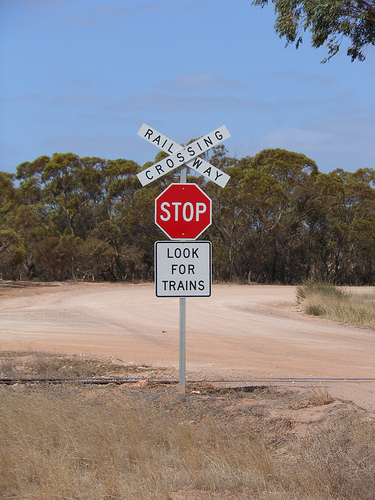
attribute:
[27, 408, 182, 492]
dry grass — dead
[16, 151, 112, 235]
tree — pictured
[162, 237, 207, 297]
sign — black , white 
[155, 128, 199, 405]
pole — long, gray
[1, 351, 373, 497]
brown grass — overgrown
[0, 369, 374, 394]
train tracks — empty, bunch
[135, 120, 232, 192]
traffic sign — railway, crossing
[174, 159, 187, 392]
post — grey 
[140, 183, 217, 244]
sign — red, big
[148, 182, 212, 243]
sign — octagonal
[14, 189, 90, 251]
tree — pictured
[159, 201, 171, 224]
letter — white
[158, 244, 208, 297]
sign — white, black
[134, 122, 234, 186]
sign — black, white, railroad crossing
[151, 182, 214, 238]
sign — black, white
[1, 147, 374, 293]
trees — green, dark green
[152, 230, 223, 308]
sign — long, grey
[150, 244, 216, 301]
sign — white, black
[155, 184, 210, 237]
sign — red, white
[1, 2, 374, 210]
sky — blue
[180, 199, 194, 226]
letter — white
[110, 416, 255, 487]
brown grass — dead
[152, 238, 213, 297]
sign — black, white